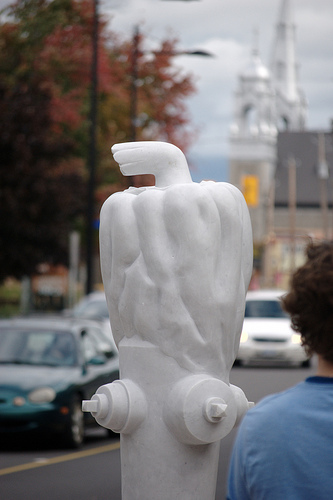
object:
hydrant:
[82, 138, 256, 499]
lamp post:
[127, 23, 214, 190]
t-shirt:
[222, 370, 332, 499]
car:
[231, 289, 311, 368]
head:
[279, 239, 333, 369]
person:
[225, 239, 333, 499]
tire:
[66, 398, 86, 449]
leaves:
[21, 38, 97, 79]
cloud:
[141, 0, 332, 120]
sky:
[0, 0, 333, 186]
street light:
[188, 50, 214, 60]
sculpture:
[82, 138, 255, 499]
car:
[0, 318, 120, 445]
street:
[2, 283, 308, 497]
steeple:
[273, 0, 305, 128]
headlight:
[28, 385, 56, 403]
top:
[98, 139, 255, 373]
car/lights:
[239, 329, 249, 346]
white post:
[81, 139, 259, 497]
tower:
[227, 24, 276, 241]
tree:
[13, 7, 80, 251]